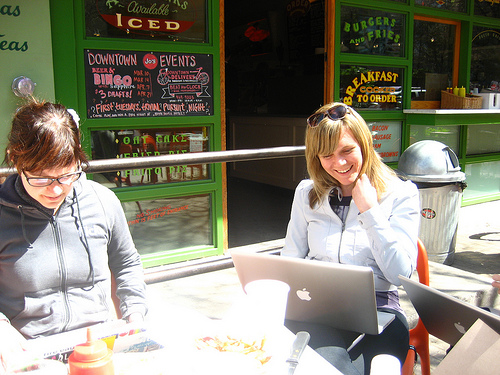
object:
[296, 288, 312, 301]
apple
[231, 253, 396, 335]
laptop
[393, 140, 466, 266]
garbage can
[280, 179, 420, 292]
jacket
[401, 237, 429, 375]
chair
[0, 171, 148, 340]
hoodie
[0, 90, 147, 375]
woman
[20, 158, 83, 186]
glasses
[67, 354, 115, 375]
ketchup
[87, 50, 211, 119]
sign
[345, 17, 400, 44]
sign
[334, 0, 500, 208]
window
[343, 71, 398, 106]
sign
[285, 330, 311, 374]
knife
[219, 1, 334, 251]
door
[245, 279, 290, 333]
container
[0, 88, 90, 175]
hair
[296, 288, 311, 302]
logo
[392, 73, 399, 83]
letters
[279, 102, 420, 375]
ladies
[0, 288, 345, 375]
table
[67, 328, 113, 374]
bottle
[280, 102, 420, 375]
woman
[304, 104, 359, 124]
sunlasses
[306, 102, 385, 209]
head